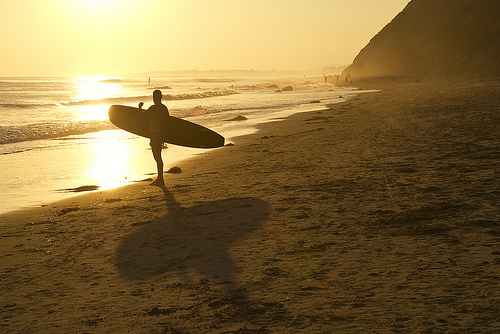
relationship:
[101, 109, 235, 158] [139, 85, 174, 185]
surfboard carried by surfer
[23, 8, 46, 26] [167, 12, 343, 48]
clouds on sky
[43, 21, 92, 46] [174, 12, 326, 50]
clouds on sky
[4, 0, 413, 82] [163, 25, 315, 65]
clouds on sky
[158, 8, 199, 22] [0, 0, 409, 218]
clouds on sky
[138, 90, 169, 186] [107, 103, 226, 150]
surfer carrying board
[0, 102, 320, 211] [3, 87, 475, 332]
sand on beach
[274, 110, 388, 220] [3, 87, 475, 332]
sand on beach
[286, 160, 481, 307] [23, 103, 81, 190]
sand on beach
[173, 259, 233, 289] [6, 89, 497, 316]
sand on beach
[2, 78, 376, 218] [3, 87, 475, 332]
wet sand on beach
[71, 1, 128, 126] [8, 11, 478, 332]
sunset on beach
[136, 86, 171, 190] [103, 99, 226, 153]
man carrying surfboard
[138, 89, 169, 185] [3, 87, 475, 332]
man on beach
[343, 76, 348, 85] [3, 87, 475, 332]
person on beach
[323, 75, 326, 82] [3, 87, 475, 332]
person on beach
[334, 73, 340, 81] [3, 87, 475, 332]
person on beach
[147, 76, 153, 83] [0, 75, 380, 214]
paddle surfer on water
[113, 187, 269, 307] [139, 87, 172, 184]
shadow of man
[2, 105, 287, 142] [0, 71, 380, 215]
wave in ocean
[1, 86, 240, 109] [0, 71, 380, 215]
wave in ocean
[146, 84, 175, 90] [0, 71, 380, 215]
wave in ocean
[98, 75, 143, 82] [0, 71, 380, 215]
wave in ocean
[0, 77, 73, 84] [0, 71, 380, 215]
wave in ocean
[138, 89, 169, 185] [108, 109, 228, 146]
man carrying surfboard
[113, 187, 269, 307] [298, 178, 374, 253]
shadow on ground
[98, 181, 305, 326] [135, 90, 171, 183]
shadow of man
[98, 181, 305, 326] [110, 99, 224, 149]
shadow of surfboard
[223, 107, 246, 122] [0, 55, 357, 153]
rock in water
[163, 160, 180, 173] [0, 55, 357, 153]
rock in water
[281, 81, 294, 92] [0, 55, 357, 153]
rock in water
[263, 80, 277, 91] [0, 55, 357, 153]
rock in water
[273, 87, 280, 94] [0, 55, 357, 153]
rock in water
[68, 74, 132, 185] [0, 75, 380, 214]
sun reflecting on water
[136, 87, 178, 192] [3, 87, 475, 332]
surfer standing on beach